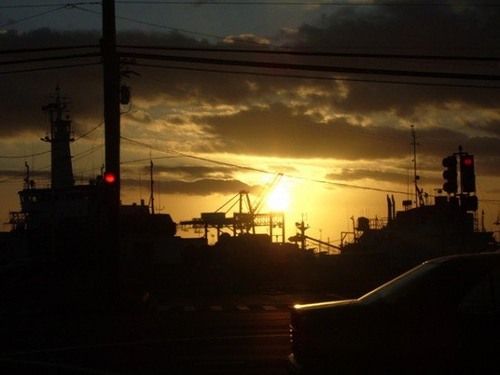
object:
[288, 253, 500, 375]
car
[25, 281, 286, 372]
street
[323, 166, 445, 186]
clouds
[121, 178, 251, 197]
clouds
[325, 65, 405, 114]
clouds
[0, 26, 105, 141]
clouds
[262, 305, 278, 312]
lines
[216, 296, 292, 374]
road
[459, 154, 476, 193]
light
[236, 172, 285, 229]
crane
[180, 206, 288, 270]
car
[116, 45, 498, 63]
lines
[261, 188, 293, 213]
sun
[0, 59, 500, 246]
sky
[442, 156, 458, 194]
light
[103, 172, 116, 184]
light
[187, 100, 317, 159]
clouds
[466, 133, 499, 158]
clouds